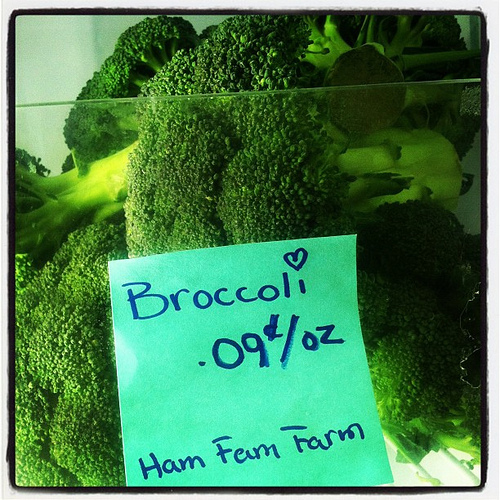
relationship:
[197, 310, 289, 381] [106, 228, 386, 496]
price on paper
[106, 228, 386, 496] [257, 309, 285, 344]
paper on sign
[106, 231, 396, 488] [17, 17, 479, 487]
note on brocolli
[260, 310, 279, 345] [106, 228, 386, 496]
writing on paper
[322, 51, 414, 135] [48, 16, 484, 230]
base on broccoli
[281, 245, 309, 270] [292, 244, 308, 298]
heart used as i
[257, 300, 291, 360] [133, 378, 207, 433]
sign on paper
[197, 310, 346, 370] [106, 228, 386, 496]
price on paper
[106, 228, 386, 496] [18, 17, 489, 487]
paper of broccoli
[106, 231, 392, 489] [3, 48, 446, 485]
note on broccoli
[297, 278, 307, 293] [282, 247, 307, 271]
i with a heart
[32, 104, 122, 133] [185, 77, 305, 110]
edge of a pane of glass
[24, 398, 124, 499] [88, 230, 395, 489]
edge of a card